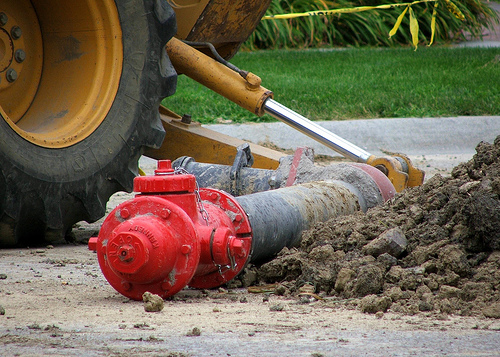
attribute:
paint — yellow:
[165, 26, 310, 128]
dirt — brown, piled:
[311, 174, 492, 294]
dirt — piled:
[295, 202, 470, 325]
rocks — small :
[70, 212, 253, 307]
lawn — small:
[161, 46, 498, 117]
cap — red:
[83, 192, 173, 278]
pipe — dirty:
[98, 140, 408, 299]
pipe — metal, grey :
[87, 149, 411, 300]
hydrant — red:
[86, 160, 251, 299]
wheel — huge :
[0, 4, 184, 244]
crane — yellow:
[151, 6, 316, 176]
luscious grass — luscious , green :
[316, 50, 480, 97]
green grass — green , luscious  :
[266, 55, 493, 103]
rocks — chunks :
[140, 132, 497, 337]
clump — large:
[358, 222, 415, 260]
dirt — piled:
[259, 130, 499, 325]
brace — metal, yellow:
[124, 30, 426, 217]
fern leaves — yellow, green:
[232, 1, 499, 51]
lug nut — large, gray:
[6, 65, 26, 95]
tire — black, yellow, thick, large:
[0, 0, 174, 246]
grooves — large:
[140, 2, 180, 164]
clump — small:
[141, 288, 161, 311]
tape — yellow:
[257, 1, 467, 51]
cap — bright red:
[88, 162, 251, 302]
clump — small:
[139, 289, 166, 315]